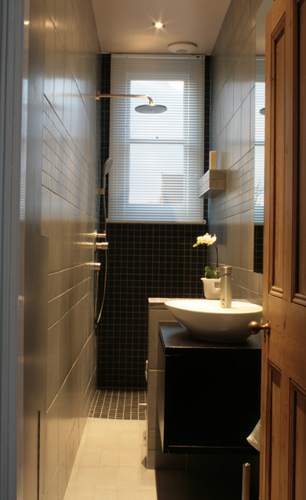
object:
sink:
[161, 286, 265, 339]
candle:
[206, 148, 220, 173]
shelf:
[196, 166, 229, 201]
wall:
[110, 226, 196, 292]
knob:
[95, 240, 108, 251]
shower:
[87, 52, 213, 417]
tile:
[119, 237, 180, 285]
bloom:
[193, 232, 218, 251]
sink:
[159, 291, 260, 346]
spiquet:
[110, 70, 162, 121]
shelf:
[195, 166, 227, 192]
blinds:
[109, 54, 206, 220]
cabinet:
[243, 40, 304, 344]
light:
[153, 19, 165, 32]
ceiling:
[92, 0, 231, 61]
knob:
[91, 260, 103, 273]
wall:
[29, 1, 102, 498]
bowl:
[171, 277, 251, 346]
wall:
[52, 64, 103, 137]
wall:
[134, 231, 189, 285]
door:
[254, 1, 302, 390]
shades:
[103, 50, 206, 222]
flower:
[193, 231, 218, 249]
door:
[258, 0, 304, 498]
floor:
[65, 380, 148, 498]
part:
[88, 385, 144, 420]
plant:
[190, 232, 223, 283]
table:
[144, 289, 246, 470]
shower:
[88, 77, 172, 125]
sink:
[159, 262, 261, 346]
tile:
[97, 419, 134, 486]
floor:
[83, 386, 144, 499]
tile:
[96, 52, 209, 389]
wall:
[1, 0, 265, 495]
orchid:
[186, 230, 221, 275]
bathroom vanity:
[143, 313, 293, 480]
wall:
[95, 50, 212, 382]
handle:
[241, 459, 251, 499]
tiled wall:
[1, 0, 100, 498]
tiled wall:
[207, 2, 253, 293]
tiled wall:
[100, 225, 201, 404]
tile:
[112, 249, 144, 376]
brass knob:
[247, 317, 271, 334]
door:
[262, 0, 304, 498]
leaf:
[192, 237, 227, 280]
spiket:
[194, 269, 235, 373]